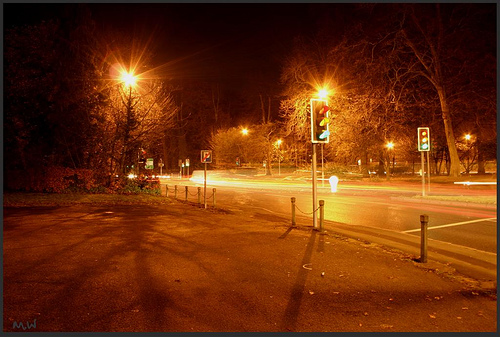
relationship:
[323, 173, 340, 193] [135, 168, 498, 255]
light on road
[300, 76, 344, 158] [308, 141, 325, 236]
light on pole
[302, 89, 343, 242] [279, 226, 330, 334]
light post has shadow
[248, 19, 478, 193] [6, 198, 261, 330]
tree has shadow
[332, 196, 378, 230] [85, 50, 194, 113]
glare from a light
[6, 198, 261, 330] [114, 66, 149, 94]
shadow cast by streetlight